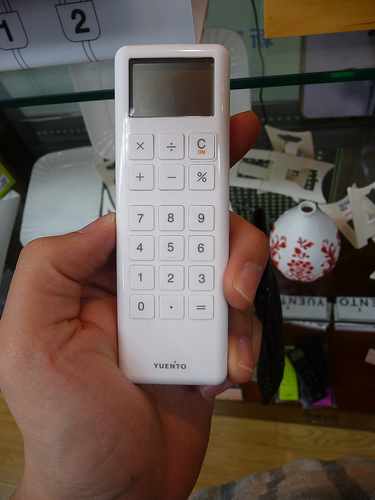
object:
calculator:
[113, 43, 231, 387]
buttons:
[129, 294, 156, 320]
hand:
[0, 108, 269, 497]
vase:
[269, 201, 341, 282]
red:
[291, 241, 312, 257]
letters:
[54, 4, 101, 42]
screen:
[128, 59, 214, 116]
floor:
[2, 419, 364, 498]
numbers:
[0, 16, 23, 55]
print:
[270, 234, 288, 267]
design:
[287, 236, 316, 283]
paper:
[70, 4, 192, 62]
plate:
[19, 146, 104, 254]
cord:
[251, 3, 266, 103]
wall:
[7, 3, 364, 124]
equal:
[188, 293, 214, 321]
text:
[0, 8, 119, 87]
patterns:
[320, 239, 337, 277]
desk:
[25, 116, 375, 427]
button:
[188, 131, 217, 162]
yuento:
[154, 361, 187, 370]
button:
[159, 204, 185, 232]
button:
[129, 205, 155, 231]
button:
[127, 134, 153, 160]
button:
[159, 133, 185, 159]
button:
[129, 166, 152, 189]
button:
[159, 162, 186, 195]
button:
[188, 164, 214, 190]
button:
[128, 236, 156, 261]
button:
[158, 235, 184, 263]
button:
[188, 233, 215, 263]